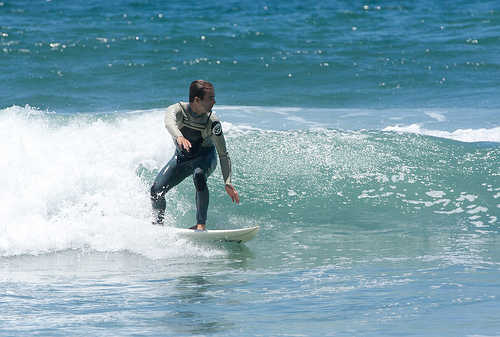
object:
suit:
[149, 100, 236, 229]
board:
[104, 210, 262, 245]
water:
[90, 156, 314, 292]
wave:
[0, 104, 500, 262]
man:
[146, 78, 243, 232]